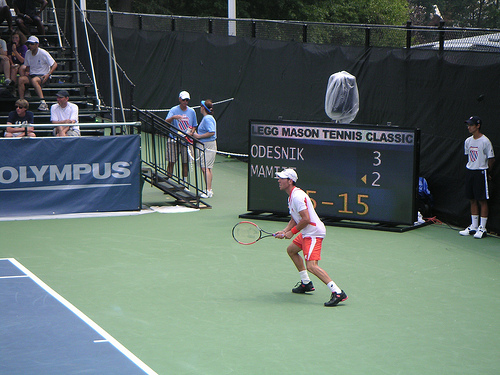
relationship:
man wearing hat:
[272, 166, 347, 308] [274, 167, 299, 182]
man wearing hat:
[161, 89, 197, 192] [178, 90, 191, 100]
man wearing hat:
[16, 35, 59, 109] [26, 35, 41, 43]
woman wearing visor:
[195, 97, 216, 199] [200, 99, 213, 114]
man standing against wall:
[458, 114, 497, 240] [54, 1, 500, 237]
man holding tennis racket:
[272, 166, 347, 308] [231, 221, 278, 247]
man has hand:
[272, 166, 347, 308] [283, 229, 295, 240]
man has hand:
[272, 166, 347, 308] [273, 230, 288, 239]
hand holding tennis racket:
[283, 229, 295, 240] [231, 221, 278, 247]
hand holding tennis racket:
[273, 230, 288, 239] [231, 221, 278, 247]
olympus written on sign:
[0, 162, 131, 185] [1, 137, 141, 215]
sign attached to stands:
[1, 137, 141, 215] [2, 1, 139, 136]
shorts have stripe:
[293, 233, 325, 261] [306, 237, 317, 259]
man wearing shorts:
[272, 166, 347, 308] [293, 233, 325, 261]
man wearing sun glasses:
[161, 89, 197, 192] [181, 97, 191, 103]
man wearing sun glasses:
[16, 35, 59, 109] [27, 41, 36, 46]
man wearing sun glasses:
[3, 99, 37, 138] [15, 104, 24, 110]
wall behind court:
[54, 1, 500, 237] [1, 109, 500, 373]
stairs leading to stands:
[131, 105, 211, 209] [2, 1, 139, 136]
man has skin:
[272, 166, 347, 308] [305, 260, 337, 285]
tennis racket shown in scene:
[231, 221, 278, 247] [2, 0, 499, 374]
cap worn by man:
[464, 116, 483, 127] [458, 114, 497, 240]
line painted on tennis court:
[8, 257, 159, 375] [1, 259, 155, 375]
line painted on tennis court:
[92, 338, 106, 344] [1, 259, 155, 375]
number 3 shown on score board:
[372, 150, 382, 167] [246, 118, 419, 227]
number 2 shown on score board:
[370, 171, 381, 189] [246, 118, 419, 227]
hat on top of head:
[274, 167, 299, 182] [274, 168, 298, 192]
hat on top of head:
[178, 90, 191, 100] [178, 90, 191, 107]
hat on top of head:
[26, 35, 41, 43] [25, 35, 40, 51]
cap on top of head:
[464, 116, 483, 127] [464, 114, 482, 135]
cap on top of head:
[54, 89, 69, 98] [54, 89, 70, 106]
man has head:
[272, 166, 347, 308] [274, 168, 298, 192]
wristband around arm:
[290, 225, 299, 234] [291, 197, 311, 236]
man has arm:
[272, 166, 347, 308] [291, 197, 311, 236]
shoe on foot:
[324, 291, 348, 306] [324, 288, 348, 306]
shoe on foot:
[290, 281, 316, 294] [291, 279, 317, 294]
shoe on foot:
[473, 226, 486, 239] [473, 225, 487, 240]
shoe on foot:
[459, 226, 475, 235] [458, 226, 481, 235]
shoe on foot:
[36, 102, 48, 110] [37, 102, 50, 111]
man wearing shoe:
[272, 166, 347, 308] [324, 291, 348, 306]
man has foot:
[272, 166, 347, 308] [324, 288, 348, 306]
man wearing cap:
[49, 89, 82, 137] [54, 89, 69, 98]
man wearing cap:
[458, 114, 497, 240] [464, 116, 483, 127]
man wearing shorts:
[458, 114, 497, 240] [464, 166, 491, 201]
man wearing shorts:
[16, 35, 59, 109] [25, 72, 50, 82]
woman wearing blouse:
[195, 97, 216, 199] [198, 116, 218, 143]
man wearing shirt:
[161, 89, 197, 192] [166, 105, 198, 140]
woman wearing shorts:
[195, 97, 216, 199] [197, 140, 218, 170]